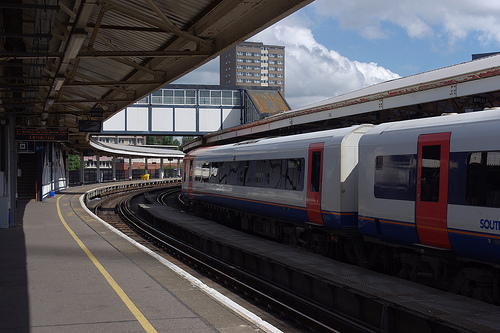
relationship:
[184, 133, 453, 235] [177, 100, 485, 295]
door of a passenger train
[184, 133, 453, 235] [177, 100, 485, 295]
door leading to passenger train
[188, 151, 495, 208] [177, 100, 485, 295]
window built into passenger train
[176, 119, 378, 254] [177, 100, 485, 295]
car attached to passenger train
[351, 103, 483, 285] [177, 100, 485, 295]
car attached to passenger train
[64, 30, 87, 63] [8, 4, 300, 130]
light fixture mounted on ceiling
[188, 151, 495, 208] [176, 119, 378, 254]
window built into car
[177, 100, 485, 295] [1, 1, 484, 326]
passenger train pulled into train station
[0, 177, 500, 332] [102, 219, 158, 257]
platform has edge